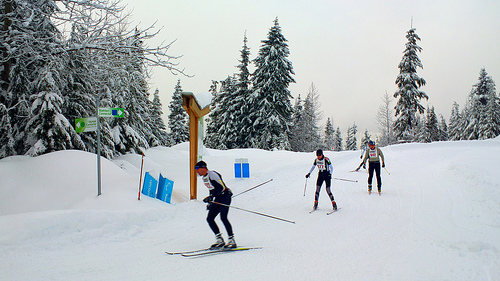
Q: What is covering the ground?
A: Snow.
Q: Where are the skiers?
A: In the image.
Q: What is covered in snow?
A: The ground and trees.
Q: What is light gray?
A: The sky.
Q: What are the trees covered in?
A: Snow.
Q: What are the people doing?
A: Skiing.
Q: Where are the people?
A: On a slope.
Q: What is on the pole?
A: Signs.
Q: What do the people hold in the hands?
A: Ski poles.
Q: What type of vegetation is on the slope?
A: Trees.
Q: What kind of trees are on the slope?
A: Pine trees.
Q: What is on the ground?
A: Snow.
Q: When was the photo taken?
A: During the daytime.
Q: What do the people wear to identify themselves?
A: Numbers.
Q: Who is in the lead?
A: The man.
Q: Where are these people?
A: Ski Slope.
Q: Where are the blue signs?
A: To the people's right.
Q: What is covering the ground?
A: Snow.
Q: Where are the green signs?
A: On metal pole.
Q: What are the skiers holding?
A: Ski poles.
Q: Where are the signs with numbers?
A: On skiers.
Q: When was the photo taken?
A: Daytime.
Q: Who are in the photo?
A: Three people.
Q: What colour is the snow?
A: White.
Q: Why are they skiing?
A: Racing.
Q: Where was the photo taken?
A: On a ski slope.